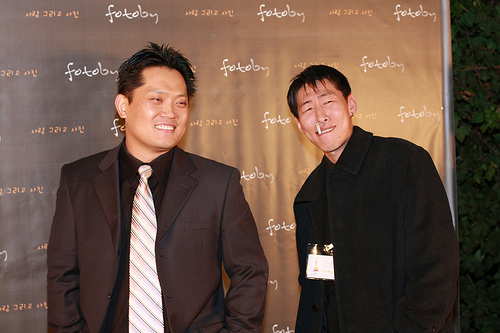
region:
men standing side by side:
[51, 38, 468, 325]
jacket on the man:
[28, 150, 289, 330]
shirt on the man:
[115, 148, 166, 330]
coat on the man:
[291, 140, 475, 331]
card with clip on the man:
[292, 244, 351, 286]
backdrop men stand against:
[7, 20, 432, 324]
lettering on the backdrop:
[211, 41, 271, 83]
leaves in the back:
[456, 17, 498, 329]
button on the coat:
[308, 295, 324, 324]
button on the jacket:
[99, 283, 119, 310]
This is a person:
[44, 32, 264, 329]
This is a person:
[280, 54, 473, 329]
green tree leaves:
[455, 3, 497, 330]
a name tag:
[302, 243, 342, 283]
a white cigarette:
[312, 120, 322, 137]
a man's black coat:
[292, 128, 462, 332]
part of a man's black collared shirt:
[117, 139, 165, 331]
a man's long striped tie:
[128, 165, 161, 332]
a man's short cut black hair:
[114, 40, 199, 105]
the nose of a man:
[158, 98, 175, 121]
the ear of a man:
[110, 95, 131, 120]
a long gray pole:
[435, 1, 455, 206]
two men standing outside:
[36, 31, 414, 331]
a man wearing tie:
[54, 23, 284, 327]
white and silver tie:
[124, 158, 204, 325]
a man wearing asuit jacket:
[97, 39, 329, 329]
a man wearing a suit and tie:
[50, 68, 215, 330]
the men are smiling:
[100, 66, 476, 327]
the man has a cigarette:
[289, 108, 397, 168]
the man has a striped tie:
[97, 134, 247, 326]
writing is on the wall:
[22, 34, 111, 164]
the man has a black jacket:
[295, 169, 487, 269]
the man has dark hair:
[254, 65, 378, 122]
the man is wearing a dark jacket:
[164, 187, 271, 314]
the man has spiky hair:
[129, 40, 186, 73]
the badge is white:
[290, 228, 339, 304]